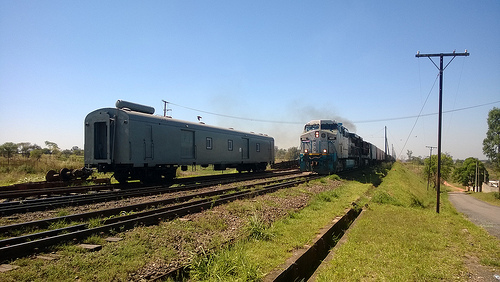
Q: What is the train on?
A: Train tracks.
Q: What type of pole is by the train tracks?
A: Electricity.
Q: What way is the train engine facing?
A: Forward.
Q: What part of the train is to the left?
A: Train car.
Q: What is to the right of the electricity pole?
A: Road.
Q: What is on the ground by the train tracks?
A: Grass.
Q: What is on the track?
A: A silver train car.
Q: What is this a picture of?
A: Trains.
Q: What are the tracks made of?
A: Steel.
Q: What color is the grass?
A: Green.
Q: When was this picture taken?
A: Daytime.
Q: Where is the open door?
A: The small train.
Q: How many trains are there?
A: Two.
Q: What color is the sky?
A: Blue.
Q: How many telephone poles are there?
A: Two.